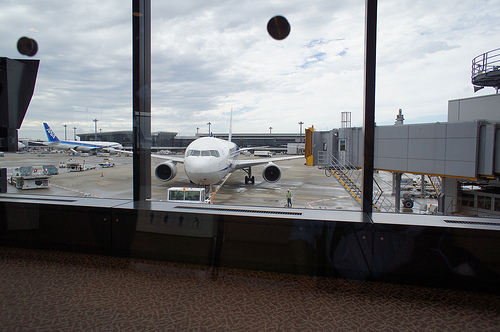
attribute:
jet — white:
[152, 134, 304, 186]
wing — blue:
[102, 146, 138, 155]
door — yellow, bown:
[295, 114, 335, 196]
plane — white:
[25, 119, 122, 153]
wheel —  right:
[241, 172, 261, 191]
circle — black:
[267, 15, 289, 38]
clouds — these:
[158, 23, 256, 107]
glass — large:
[171, 15, 328, 180]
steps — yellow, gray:
[328, 157, 386, 212]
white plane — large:
[102, 107, 304, 183]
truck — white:
[67, 138, 139, 182]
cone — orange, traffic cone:
[101, 174, 103, 176]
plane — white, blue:
[22, 124, 124, 155]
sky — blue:
[1, 2, 498, 129]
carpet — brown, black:
[14, 262, 211, 319]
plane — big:
[158, 101, 295, 215]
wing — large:
[235, 154, 311, 165]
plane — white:
[108, 132, 300, 192]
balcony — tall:
[465, 40, 484, 97]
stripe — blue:
[52, 140, 103, 150]